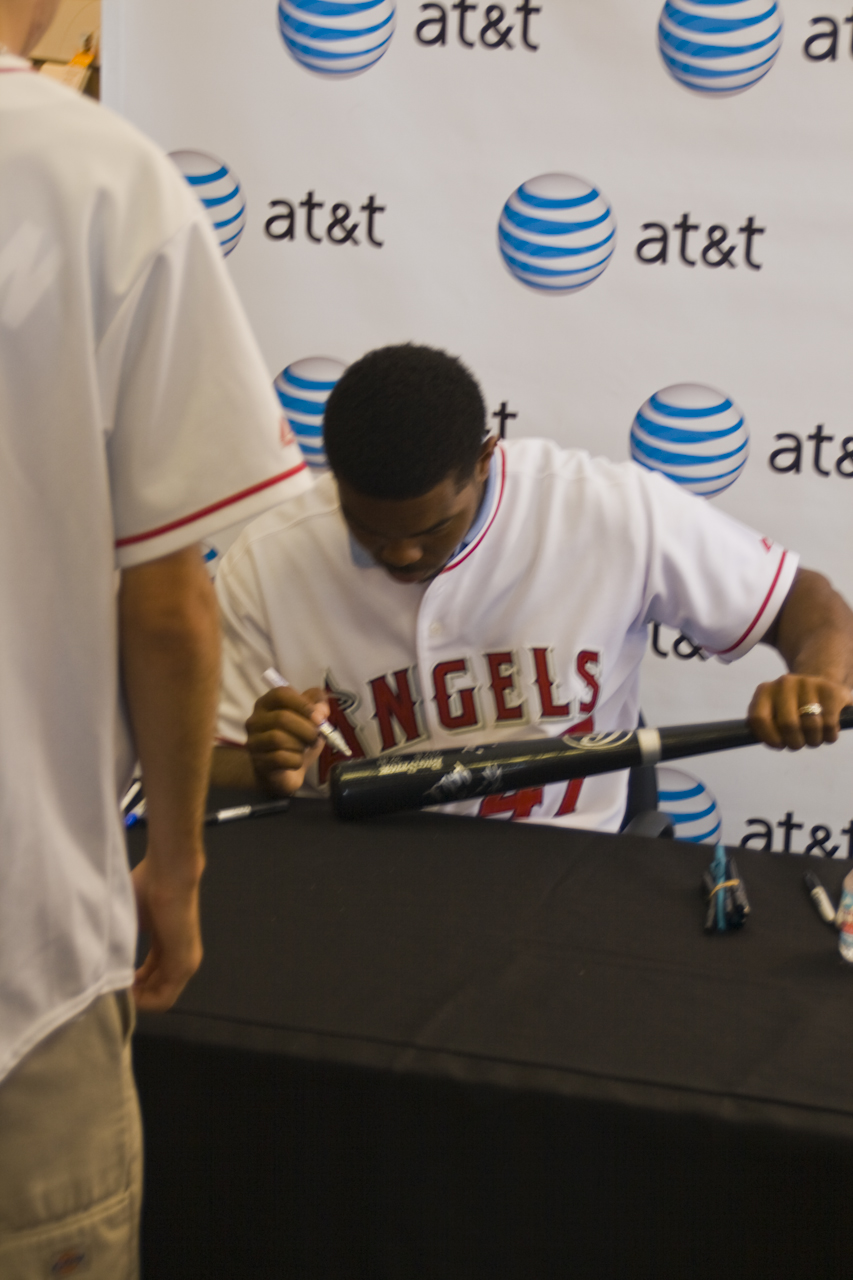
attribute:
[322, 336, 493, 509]
hair — Black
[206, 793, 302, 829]
marker — black, capped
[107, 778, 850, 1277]
cloth — Black 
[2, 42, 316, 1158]
shirt — white, short-sleeved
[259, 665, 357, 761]
marker — white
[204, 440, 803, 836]
jersey — red, white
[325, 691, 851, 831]
bat — black, silver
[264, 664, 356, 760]
pen — white